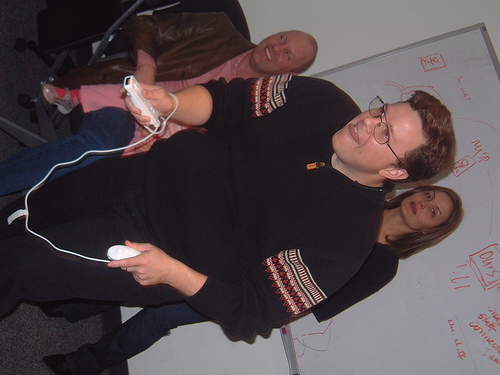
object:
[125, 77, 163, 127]
controller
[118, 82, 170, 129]
hand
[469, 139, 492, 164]
writing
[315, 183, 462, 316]
woman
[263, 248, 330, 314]
design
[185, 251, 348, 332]
sleeve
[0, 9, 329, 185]
man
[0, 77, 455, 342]
man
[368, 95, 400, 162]
glasses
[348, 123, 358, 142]
tongue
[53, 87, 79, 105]
socks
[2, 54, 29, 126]
carpet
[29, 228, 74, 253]
cord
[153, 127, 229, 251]
foreground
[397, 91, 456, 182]
hair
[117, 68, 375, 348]
sweater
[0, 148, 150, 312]
jeans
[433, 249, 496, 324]
background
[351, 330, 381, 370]
board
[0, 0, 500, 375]
photo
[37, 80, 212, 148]
child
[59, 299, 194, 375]
jeans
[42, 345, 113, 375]
shoes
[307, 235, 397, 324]
shirt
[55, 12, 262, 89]
jacket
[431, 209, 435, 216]
eyes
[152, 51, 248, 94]
shirt